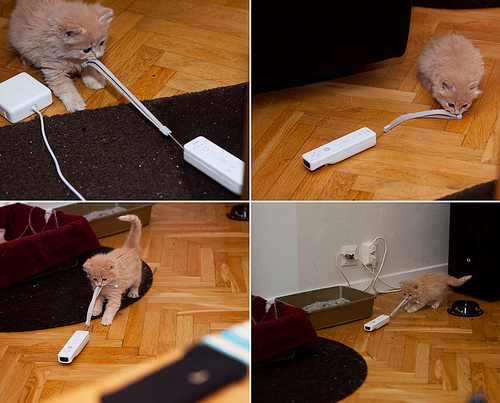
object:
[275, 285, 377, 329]
tray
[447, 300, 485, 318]
bowl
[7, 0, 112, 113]
kitty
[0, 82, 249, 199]
rug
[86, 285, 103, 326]
strap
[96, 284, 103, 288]
mouth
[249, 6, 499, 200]
ground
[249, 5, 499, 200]
floor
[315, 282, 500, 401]
floor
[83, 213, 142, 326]
kitten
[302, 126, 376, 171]
game controller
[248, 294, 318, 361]
box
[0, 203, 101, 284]
box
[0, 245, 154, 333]
carpet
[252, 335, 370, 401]
carpet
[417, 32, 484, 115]
kitten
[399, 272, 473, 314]
kitten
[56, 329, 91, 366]
controller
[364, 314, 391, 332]
controller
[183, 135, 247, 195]
controller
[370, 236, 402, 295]
wires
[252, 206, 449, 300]
wall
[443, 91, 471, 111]
face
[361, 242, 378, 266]
outlet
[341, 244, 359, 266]
outlet